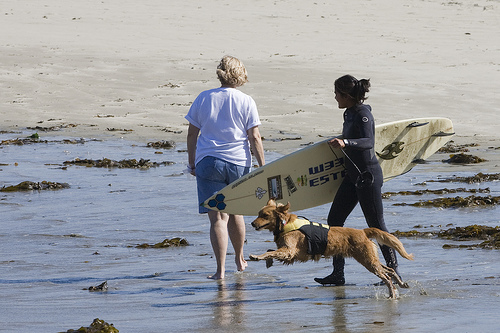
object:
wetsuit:
[326, 103, 403, 286]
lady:
[183, 56, 265, 281]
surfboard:
[204, 116, 455, 217]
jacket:
[297, 222, 327, 257]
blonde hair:
[213, 54, 249, 88]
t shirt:
[183, 85, 262, 168]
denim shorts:
[191, 156, 249, 214]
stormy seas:
[6, 32, 186, 114]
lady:
[312, 70, 402, 286]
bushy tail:
[361, 226, 411, 261]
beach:
[0, 3, 497, 331]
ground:
[419, 123, 464, 171]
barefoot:
[209, 260, 254, 280]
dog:
[247, 198, 415, 300]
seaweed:
[381, 167, 498, 250]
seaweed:
[56, 154, 176, 173]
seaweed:
[0, 180, 70, 195]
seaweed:
[58, 316, 122, 332]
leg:
[358, 246, 397, 298]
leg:
[378, 262, 407, 288]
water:
[2, 131, 499, 331]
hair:
[334, 73, 373, 107]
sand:
[0, 1, 499, 330]